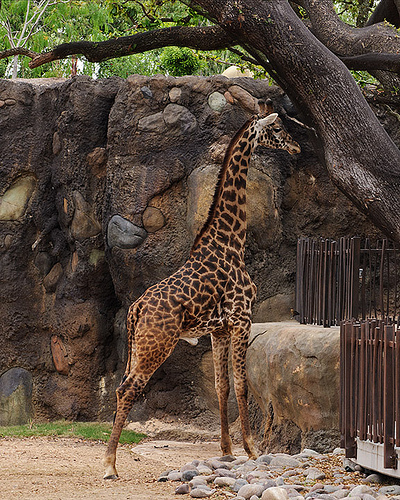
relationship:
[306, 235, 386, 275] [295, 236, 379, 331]
rails on fence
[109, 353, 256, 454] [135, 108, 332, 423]
legs of giraffe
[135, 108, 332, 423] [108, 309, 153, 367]
giraffe has tail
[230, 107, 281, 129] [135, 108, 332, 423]
head of giraffe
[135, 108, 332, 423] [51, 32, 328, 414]
giraffe in zoo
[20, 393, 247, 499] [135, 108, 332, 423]
ground near giraffe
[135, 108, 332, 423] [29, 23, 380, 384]
giraffe in pen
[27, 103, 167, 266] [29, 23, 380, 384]
rocks in pen